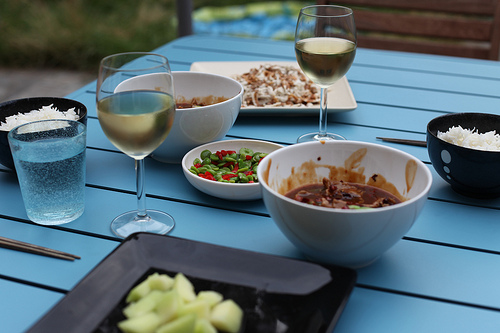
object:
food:
[119, 267, 241, 332]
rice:
[2, 99, 82, 130]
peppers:
[192, 170, 218, 182]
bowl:
[180, 136, 282, 202]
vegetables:
[192, 148, 264, 182]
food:
[173, 94, 230, 111]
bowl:
[112, 69, 247, 164]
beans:
[202, 157, 211, 165]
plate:
[23, 232, 359, 333]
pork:
[313, 190, 353, 209]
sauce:
[366, 180, 399, 195]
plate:
[190, 57, 360, 117]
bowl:
[255, 139, 434, 270]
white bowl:
[280, 114, 412, 270]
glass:
[289, 3, 363, 145]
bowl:
[425, 110, 499, 202]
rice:
[435, 125, 499, 150]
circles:
[439, 149, 454, 166]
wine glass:
[96, 52, 174, 237]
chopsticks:
[1, 237, 82, 262]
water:
[10, 150, 86, 220]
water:
[24, 138, 79, 210]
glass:
[292, 4, 357, 143]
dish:
[225, 63, 327, 111]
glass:
[6, 118, 86, 228]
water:
[12, 137, 85, 226]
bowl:
[0, 95, 87, 173]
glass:
[92, 50, 175, 235]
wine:
[95, 90, 172, 160]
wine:
[293, 36, 356, 87]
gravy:
[284, 173, 404, 211]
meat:
[335, 184, 369, 203]